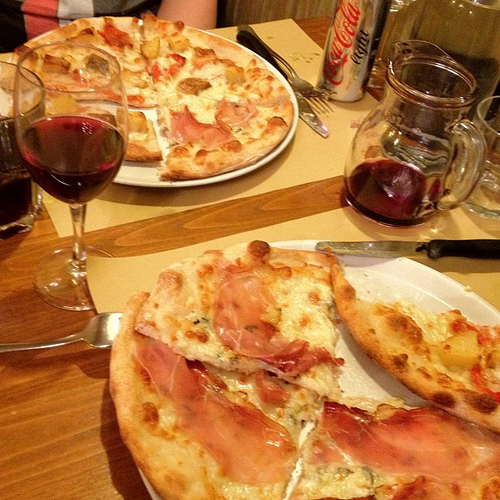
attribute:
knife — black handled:
[297, 98, 322, 137]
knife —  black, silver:
[317, 204, 498, 265]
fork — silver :
[1, 312, 123, 354]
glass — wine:
[1, 58, 51, 244]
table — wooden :
[0, 13, 500, 495]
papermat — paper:
[12, 10, 432, 231]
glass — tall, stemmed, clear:
[7, 34, 134, 314]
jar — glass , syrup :
[331, 20, 488, 245]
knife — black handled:
[235, 13, 332, 145]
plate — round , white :
[21, 16, 312, 213]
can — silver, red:
[311, 2, 392, 102]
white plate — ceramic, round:
[137, 233, 498, 498]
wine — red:
[16, 115, 125, 202]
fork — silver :
[206, 13, 413, 177]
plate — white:
[15, 11, 298, 191]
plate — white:
[107, 237, 494, 498]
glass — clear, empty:
[461, 94, 499, 218]